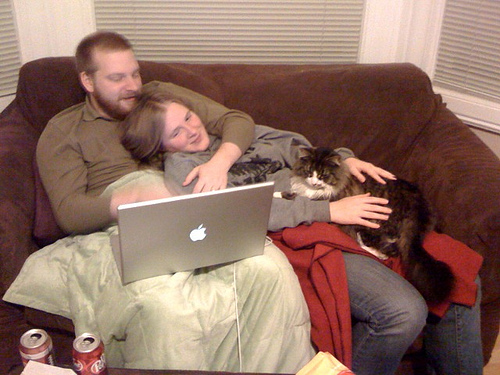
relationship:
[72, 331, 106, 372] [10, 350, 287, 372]
can on table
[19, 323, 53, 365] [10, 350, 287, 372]
can on table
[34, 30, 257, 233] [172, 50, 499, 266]
man cuddling on couch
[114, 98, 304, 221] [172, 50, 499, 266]
person cuddling on couch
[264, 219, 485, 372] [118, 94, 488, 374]
blanket on person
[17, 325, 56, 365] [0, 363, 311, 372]
can on table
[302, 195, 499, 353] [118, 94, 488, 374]
jeans on person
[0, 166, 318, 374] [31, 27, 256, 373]
blanket on man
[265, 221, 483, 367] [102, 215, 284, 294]
blanket on lap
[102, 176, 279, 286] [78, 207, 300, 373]
laptop on lap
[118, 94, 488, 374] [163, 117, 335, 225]
person wearing sweatshirt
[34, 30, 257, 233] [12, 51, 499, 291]
man sitting on couch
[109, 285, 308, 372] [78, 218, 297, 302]
blanket on lap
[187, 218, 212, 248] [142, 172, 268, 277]
logo on computer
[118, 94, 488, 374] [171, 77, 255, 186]
person lying in arm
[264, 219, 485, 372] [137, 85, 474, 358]
blanket on woman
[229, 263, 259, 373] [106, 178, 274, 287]
white cable on laptop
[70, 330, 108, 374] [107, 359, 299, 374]
can on table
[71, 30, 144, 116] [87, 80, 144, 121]
man has beard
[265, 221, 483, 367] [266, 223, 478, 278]
blanket on lap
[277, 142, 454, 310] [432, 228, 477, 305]
cat on blanket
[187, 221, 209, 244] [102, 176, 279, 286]
logo on laptop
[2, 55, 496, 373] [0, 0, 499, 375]
couch in livingroom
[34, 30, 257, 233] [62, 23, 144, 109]
man with hair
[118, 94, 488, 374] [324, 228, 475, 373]
person wearing pants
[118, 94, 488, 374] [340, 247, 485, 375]
person wearing jeans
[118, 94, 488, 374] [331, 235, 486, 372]
person wearing jeans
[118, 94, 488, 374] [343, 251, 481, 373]
person wearing jeans